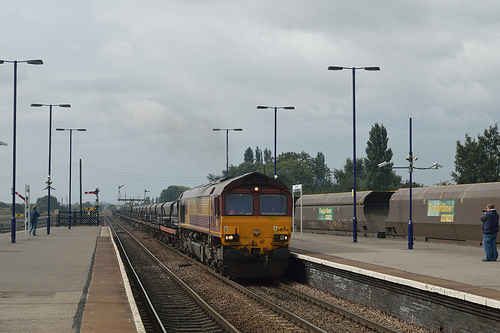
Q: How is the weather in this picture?
A: It is cloudy.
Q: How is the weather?
A: It is cloudy.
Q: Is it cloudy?
A: Yes, it is cloudy.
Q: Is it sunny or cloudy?
A: It is cloudy.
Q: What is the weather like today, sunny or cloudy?
A: It is cloudy.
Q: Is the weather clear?
A: No, it is cloudy.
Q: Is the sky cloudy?
A: Yes, the sky is cloudy.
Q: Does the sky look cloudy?
A: Yes, the sky is cloudy.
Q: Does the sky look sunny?
A: No, the sky is cloudy.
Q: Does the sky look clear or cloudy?
A: The sky is cloudy.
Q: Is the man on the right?
A: Yes, the man is on the right of the image.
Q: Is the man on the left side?
A: No, the man is on the right of the image.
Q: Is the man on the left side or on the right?
A: The man is on the right of the image.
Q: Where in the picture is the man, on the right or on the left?
A: The man is on the right of the image.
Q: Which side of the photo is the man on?
A: The man is on the right of the image.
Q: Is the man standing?
A: Yes, the man is standing.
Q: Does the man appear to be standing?
A: Yes, the man is standing.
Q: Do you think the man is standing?
A: Yes, the man is standing.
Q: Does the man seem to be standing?
A: Yes, the man is standing.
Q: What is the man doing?
A: The man is standing.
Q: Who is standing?
A: The man is standing.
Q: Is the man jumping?
A: No, the man is standing.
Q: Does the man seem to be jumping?
A: No, the man is standing.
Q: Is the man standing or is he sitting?
A: The man is standing.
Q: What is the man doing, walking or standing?
A: The man is standing.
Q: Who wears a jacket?
A: The man wears a jacket.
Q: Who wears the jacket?
A: The man wears a jacket.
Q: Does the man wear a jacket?
A: Yes, the man wears a jacket.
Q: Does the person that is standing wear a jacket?
A: Yes, the man wears a jacket.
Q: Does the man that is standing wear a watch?
A: No, the man wears a jacket.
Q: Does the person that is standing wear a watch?
A: No, the man wears a jacket.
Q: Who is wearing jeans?
A: The man is wearing jeans.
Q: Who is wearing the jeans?
A: The man is wearing jeans.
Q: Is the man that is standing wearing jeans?
A: Yes, the man is wearing jeans.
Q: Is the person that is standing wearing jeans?
A: Yes, the man is wearing jeans.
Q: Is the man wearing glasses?
A: No, the man is wearing jeans.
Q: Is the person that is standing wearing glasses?
A: No, the man is wearing jeans.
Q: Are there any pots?
A: No, there are no pots.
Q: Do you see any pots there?
A: No, there are no pots.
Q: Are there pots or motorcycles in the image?
A: No, there are no pots or motorcycles.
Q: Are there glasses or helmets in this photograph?
A: No, there are no glasses or helmets.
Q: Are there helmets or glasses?
A: No, there are no glasses or helmets.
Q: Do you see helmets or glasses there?
A: No, there are no glasses or helmets.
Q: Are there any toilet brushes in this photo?
A: No, there are no toilet brushes.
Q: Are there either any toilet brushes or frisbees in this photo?
A: No, there are no toilet brushes or frisbees.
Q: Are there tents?
A: No, there are no tents.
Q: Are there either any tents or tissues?
A: No, there are no tents or tissues.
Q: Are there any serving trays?
A: No, there are no serving trays.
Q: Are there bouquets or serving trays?
A: No, there are no serving trays or bouquets.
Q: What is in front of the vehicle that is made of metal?
A: The cart is in front of the train.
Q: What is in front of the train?
A: The cart is in front of the train.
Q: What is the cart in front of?
A: The cart is in front of the train.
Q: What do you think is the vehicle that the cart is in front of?
A: The vehicle is a train.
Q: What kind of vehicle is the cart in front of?
A: The cart is in front of the train.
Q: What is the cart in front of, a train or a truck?
A: The cart is in front of a train.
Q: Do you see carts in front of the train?
A: Yes, there is a cart in front of the train.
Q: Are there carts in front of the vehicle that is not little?
A: Yes, there is a cart in front of the train.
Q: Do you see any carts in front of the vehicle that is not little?
A: Yes, there is a cart in front of the train.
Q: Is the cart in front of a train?
A: Yes, the cart is in front of a train.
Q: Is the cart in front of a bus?
A: No, the cart is in front of a train.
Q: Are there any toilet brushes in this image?
A: No, there are no toilet brushes.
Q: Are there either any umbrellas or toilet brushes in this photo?
A: No, there are no toilet brushes or umbrellas.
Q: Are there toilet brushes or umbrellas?
A: No, there are no toilet brushes or umbrellas.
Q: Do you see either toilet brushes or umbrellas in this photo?
A: No, there are no toilet brushes or umbrellas.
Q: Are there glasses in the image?
A: No, there are no glasses.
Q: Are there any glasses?
A: No, there are no glasses.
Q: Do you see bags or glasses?
A: No, there are no glasses or bags.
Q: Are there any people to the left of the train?
A: Yes, there is a person to the left of the train.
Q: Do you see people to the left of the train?
A: Yes, there is a person to the left of the train.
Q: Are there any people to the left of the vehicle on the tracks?
A: Yes, there is a person to the left of the train.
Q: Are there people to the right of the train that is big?
A: No, the person is to the left of the train.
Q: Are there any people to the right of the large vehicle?
A: No, the person is to the left of the train.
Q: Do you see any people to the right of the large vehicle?
A: No, the person is to the left of the train.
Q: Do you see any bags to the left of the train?
A: No, there is a person to the left of the train.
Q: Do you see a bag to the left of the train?
A: No, there is a person to the left of the train.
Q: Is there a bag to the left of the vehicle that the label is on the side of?
A: No, there is a person to the left of the train.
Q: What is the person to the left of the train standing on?
A: The person is standing on the platform.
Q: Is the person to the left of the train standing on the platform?
A: Yes, the person is standing on the platform.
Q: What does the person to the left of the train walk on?
A: The person walks on the platform.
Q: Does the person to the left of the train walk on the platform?
A: Yes, the person walks on the platform.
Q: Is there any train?
A: Yes, there is a train.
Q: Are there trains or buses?
A: Yes, there is a train.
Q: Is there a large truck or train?
A: Yes, there is a large train.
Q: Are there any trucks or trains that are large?
A: Yes, the train is large.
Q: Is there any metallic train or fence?
A: Yes, there is a metal train.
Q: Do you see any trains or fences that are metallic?
A: Yes, the train is metallic.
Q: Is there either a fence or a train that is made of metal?
A: Yes, the train is made of metal.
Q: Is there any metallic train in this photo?
A: Yes, there is a metal train.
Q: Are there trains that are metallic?
A: Yes, there is a train that is metallic.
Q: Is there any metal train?
A: Yes, there is a train that is made of metal.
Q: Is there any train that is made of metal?
A: Yes, there is a train that is made of metal.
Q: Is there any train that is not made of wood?
A: Yes, there is a train that is made of metal.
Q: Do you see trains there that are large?
A: Yes, there is a large train.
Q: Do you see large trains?
A: Yes, there is a large train.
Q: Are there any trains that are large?
A: Yes, there is a train that is large.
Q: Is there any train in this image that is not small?
A: Yes, there is a large train.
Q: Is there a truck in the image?
A: No, there are no trucks.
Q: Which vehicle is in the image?
A: The vehicle is a train.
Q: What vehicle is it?
A: The vehicle is a train.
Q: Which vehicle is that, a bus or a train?
A: This is a train.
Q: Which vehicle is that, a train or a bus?
A: This is a train.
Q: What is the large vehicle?
A: The vehicle is a train.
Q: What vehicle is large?
A: The vehicle is a train.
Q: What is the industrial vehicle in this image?
A: The vehicle is a train.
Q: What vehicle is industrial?
A: The vehicle is a train.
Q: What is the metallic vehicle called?
A: The vehicle is a train.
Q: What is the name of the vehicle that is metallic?
A: The vehicle is a train.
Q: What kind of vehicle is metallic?
A: The vehicle is a train.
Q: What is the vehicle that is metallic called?
A: The vehicle is a train.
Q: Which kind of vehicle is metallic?
A: The vehicle is a train.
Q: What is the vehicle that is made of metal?
A: The vehicle is a train.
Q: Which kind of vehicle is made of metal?
A: The vehicle is a train.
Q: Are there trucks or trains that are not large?
A: No, there is a train but it is large.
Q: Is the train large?
A: Yes, the train is large.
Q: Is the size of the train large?
A: Yes, the train is large.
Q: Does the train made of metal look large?
A: Yes, the train is large.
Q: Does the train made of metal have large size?
A: Yes, the train is large.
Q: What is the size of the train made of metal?
A: The train is large.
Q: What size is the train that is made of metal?
A: The train is large.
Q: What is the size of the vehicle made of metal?
A: The train is large.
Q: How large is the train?
A: The train is large.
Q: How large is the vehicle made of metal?
A: The train is large.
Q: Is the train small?
A: No, the train is large.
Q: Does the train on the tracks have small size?
A: No, the train is large.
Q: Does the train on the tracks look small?
A: No, the train is large.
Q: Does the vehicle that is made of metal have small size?
A: No, the train is large.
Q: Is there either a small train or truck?
A: No, there is a train but it is large.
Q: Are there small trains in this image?
A: No, there is a train but it is large.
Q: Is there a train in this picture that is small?
A: No, there is a train but it is large.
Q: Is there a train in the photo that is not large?
A: No, there is a train but it is large.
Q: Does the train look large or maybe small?
A: The train is large.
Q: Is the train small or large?
A: The train is large.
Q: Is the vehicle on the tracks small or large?
A: The train is large.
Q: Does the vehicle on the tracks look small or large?
A: The train is large.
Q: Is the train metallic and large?
A: Yes, the train is metallic and large.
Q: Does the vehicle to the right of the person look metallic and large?
A: Yes, the train is metallic and large.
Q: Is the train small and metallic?
A: No, the train is metallic but large.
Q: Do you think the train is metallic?
A: Yes, the train is metallic.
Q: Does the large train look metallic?
A: Yes, the train is metallic.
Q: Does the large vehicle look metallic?
A: Yes, the train is metallic.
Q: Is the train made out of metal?
A: Yes, the train is made of metal.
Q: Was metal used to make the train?
A: Yes, the train is made of metal.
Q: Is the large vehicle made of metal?
A: Yes, the train is made of metal.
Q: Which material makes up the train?
A: The train is made of metal.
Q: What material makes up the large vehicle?
A: The train is made of metal.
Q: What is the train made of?
A: The train is made of metal.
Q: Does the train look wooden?
A: No, the train is metallic.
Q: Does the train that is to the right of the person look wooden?
A: No, the train is metallic.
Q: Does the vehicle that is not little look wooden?
A: No, the train is metallic.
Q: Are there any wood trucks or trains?
A: No, there is a train but it is metallic.